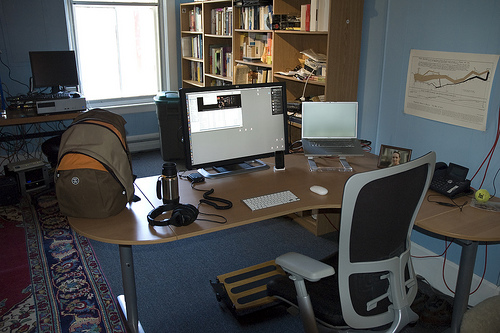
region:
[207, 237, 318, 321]
a foot rest under the desk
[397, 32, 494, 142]
a white chart on the wall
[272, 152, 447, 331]
a black and grey office chair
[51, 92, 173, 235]
a brown and orange backpack on corner of desk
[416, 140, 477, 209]
a black office phone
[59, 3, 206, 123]
a window with the sun shining threw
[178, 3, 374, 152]
large bookshelf filled with papers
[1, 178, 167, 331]
a red and blue carpet on the floor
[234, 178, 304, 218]
a small white keyboard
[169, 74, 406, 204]
two monitors on the desk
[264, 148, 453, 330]
A computer chair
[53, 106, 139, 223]
A backpack on a desk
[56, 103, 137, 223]
Orange and brown packpack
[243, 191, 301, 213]
Wireless keyboard on a desk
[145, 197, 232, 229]
Black headphones on a desk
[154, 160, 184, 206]
A silver thermos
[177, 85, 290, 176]
A large computer screen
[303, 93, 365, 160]
A small silver laptop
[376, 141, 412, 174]
A picture of a lady on the desk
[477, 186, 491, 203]
Yellow tennis ball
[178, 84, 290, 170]
Computer monitor on a wooden desk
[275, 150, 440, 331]
Comfortable chair by desk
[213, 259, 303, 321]
Footrest under desk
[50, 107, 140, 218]
Brown and orange bag on desk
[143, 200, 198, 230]
Headphones laying on desk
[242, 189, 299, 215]
Small white keyboard on desk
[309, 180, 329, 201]
white mouse is next to keyboard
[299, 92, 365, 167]
open lap top next to monitor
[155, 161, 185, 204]
metal thermos behind headph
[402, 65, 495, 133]
poster on wall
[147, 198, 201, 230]
black headphones on table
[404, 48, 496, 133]
paper graph hanging on the wall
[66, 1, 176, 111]
window with white frame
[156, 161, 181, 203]
silver cup with black lid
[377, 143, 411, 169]
framed picture on the desk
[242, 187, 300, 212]
small, white, cordless keyboard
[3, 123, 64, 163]
tangle of black wires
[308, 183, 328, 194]
white cordless mouse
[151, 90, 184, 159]
garbage can with green lid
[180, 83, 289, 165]
monitor that is turned on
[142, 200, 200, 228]
black earphones on desk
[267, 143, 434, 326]
gray and black office chair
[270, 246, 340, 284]
left arm rest on chair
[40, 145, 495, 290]
L shaped office desk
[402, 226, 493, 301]
electric cores hanging down wall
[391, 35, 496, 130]
chart taped to blue wall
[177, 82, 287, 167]
computer monitering screen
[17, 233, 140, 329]
multi-colored floor rug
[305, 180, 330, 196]
white mouse on desktop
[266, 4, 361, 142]
walnut bookshelf against blue wall